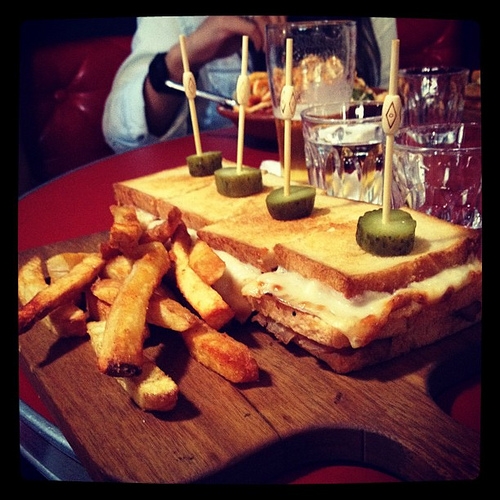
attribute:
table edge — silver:
[19, 402, 94, 492]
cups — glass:
[316, 92, 470, 214]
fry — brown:
[187, 324, 257, 386]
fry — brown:
[189, 235, 224, 282]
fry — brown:
[98, 242, 173, 377]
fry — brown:
[18, 254, 102, 334]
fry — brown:
[104, 201, 140, 252]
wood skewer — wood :
[380, 38, 401, 222]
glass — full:
[288, 82, 405, 216]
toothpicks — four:
[259, 103, 437, 194]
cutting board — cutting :
[16, 225, 481, 481]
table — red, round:
[16, 133, 196, 252]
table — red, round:
[260, 441, 409, 482]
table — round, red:
[198, 125, 237, 164]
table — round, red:
[241, 122, 280, 171]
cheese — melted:
[256, 277, 450, 319]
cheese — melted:
[126, 143, 446, 377]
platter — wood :
[18, 230, 478, 480]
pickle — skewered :
[353, 206, 417, 252]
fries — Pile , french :
[72, 226, 232, 396]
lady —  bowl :
[103, 18, 404, 153]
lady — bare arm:
[111, 19, 301, 149]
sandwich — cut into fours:
[128, 159, 493, 399]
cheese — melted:
[228, 259, 484, 346]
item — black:
[148, 50, 175, 97]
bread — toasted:
[123, 152, 463, 371]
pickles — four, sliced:
[180, 146, 418, 248]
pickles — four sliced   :
[186, 150, 418, 253]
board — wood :
[34, 236, 472, 485]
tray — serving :
[29, 171, 483, 493]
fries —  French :
[27, 207, 265, 409]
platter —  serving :
[30, 173, 484, 485]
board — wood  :
[83, 346, 300, 463]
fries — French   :
[26, 230, 260, 399]